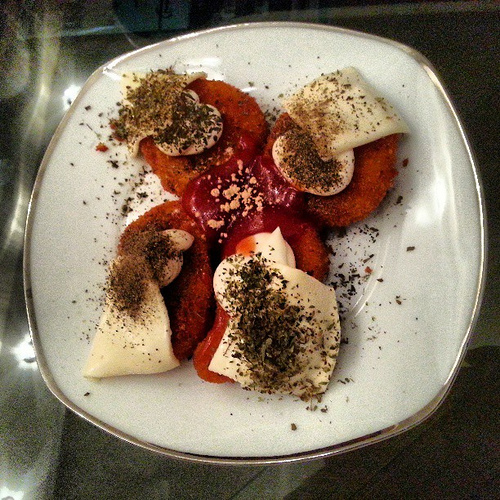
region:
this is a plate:
[429, 195, 469, 287]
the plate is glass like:
[418, 202, 473, 289]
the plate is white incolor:
[423, 218, 479, 298]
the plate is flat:
[425, 198, 477, 293]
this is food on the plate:
[111, 51, 401, 376]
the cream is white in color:
[222, 230, 297, 345]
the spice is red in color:
[183, 161, 280, 221]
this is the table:
[400, 442, 465, 498]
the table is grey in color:
[431, 410, 486, 476]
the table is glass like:
[7, 22, 65, 89]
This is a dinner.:
[59, 59, 469, 426]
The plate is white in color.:
[28, 174, 110, 276]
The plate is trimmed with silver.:
[88, 420, 411, 470]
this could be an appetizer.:
[97, 38, 379, 393]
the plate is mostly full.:
[83, 53, 425, 352]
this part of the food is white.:
[86, 313, 176, 365]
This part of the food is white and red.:
[181, 170, 299, 237]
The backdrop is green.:
[14, 435, 134, 494]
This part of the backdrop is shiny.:
[23, 72, 83, 117]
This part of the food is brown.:
[286, 139, 333, 192]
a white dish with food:
[19, 18, 488, 469]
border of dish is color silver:
[16, 8, 493, 470]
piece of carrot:
[146, 72, 268, 192]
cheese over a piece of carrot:
[264, 58, 419, 165]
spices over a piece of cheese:
[203, 252, 350, 400]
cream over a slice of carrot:
[233, 222, 310, 265]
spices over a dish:
[342, 229, 437, 339]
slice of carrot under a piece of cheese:
[111, 198, 213, 358]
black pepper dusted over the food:
[73, 59, 404, 319]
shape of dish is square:
[16, 13, 498, 476]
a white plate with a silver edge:
[22, 20, 488, 470]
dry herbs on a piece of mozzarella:
[153, 89, 225, 158]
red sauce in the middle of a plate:
[186, 158, 301, 244]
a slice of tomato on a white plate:
[132, 75, 266, 191]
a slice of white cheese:
[84, 253, 181, 379]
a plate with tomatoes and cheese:
[26, 27, 481, 467]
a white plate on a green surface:
[19, 16, 490, 467]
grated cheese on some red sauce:
[203, 145, 264, 242]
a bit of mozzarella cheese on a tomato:
[272, 124, 355, 196]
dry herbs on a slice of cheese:
[279, 60, 411, 161]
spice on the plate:
[408, 243, 421, 263]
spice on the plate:
[289, 422, 307, 437]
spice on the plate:
[317, 402, 329, 421]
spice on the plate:
[341, 379, 355, 397]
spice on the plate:
[86, 389, 103, 399]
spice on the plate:
[71, 295, 86, 307]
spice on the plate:
[80, 197, 89, 211]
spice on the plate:
[258, 325, 271, 340]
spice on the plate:
[107, 160, 117, 172]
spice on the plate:
[66, 155, 85, 173]